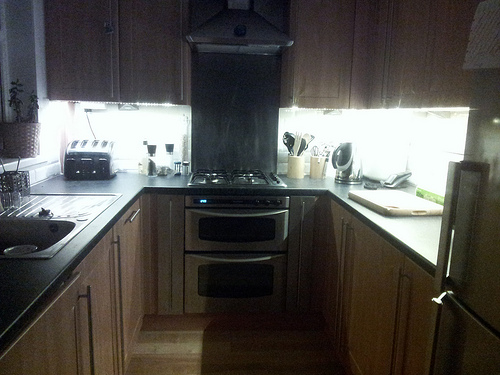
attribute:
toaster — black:
[58, 131, 126, 186]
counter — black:
[50, 149, 375, 198]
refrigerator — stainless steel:
[420, 93, 485, 363]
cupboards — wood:
[52, 8, 174, 106]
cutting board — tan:
[345, 171, 450, 222]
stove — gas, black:
[191, 158, 291, 191]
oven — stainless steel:
[176, 190, 305, 319]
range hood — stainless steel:
[176, 8, 308, 74]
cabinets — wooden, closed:
[42, 1, 499, 79]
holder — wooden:
[313, 155, 330, 180]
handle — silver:
[436, 149, 451, 294]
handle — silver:
[411, 291, 450, 371]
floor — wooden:
[129, 312, 329, 370]